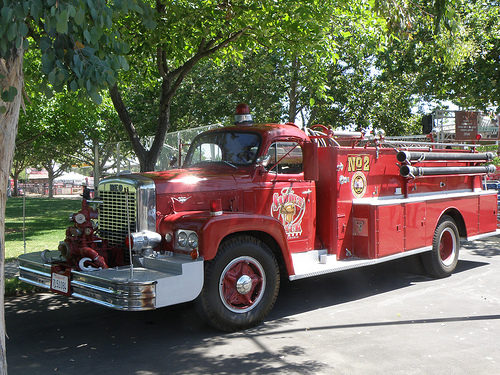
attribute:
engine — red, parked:
[11, 95, 498, 334]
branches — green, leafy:
[1, 0, 499, 177]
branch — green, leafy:
[171, 51, 232, 72]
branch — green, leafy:
[171, 11, 234, 27]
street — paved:
[15, 204, 499, 367]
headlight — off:
[174, 229, 204, 250]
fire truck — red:
[15, 114, 499, 343]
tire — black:
[201, 240, 281, 330]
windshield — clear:
[181, 131, 268, 178]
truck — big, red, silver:
[15, 99, 499, 336]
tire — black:
[418, 220, 463, 274]